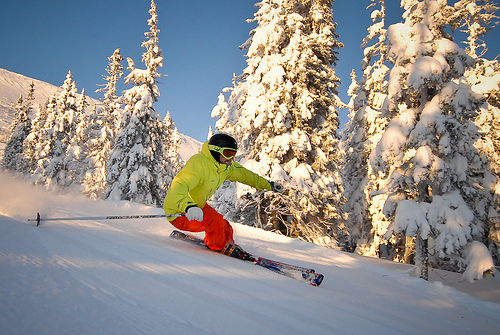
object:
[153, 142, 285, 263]
man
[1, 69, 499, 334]
hill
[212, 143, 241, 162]
goggles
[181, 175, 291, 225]
gloves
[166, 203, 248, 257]
pants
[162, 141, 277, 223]
jacket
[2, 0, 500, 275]
trees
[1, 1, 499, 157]
sky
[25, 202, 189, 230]
ski pole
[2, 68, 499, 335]
snow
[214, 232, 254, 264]
boots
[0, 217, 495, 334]
shadow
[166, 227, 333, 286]
skis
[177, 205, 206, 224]
right hand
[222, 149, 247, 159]
lenses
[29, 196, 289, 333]
tracks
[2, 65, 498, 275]
background